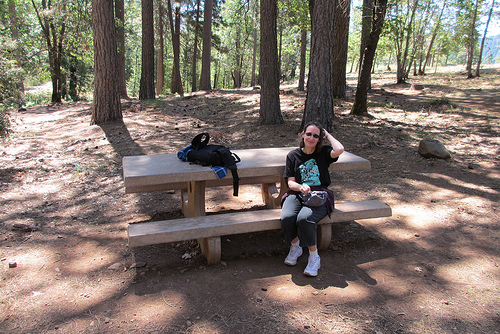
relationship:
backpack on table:
[186, 129, 245, 182] [139, 156, 165, 185]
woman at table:
[286, 129, 336, 281] [139, 156, 165, 185]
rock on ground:
[422, 124, 449, 160] [48, 214, 85, 256]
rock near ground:
[422, 124, 449, 160] [48, 214, 85, 256]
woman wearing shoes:
[286, 129, 336, 281] [284, 245, 326, 275]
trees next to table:
[44, 5, 115, 52] [139, 156, 165, 185]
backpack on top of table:
[186, 129, 245, 182] [139, 156, 165, 185]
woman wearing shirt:
[286, 129, 336, 281] [286, 146, 340, 204]